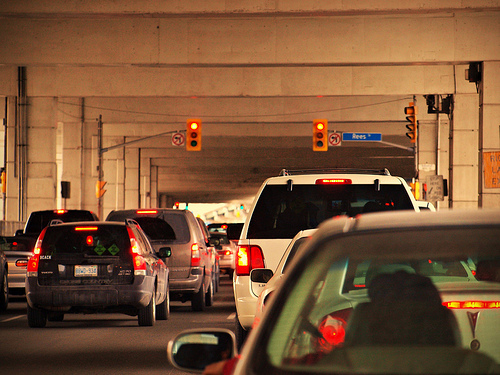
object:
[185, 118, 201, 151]
light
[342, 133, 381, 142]
sign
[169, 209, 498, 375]
car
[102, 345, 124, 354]
street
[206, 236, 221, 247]
hand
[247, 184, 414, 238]
window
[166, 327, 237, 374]
mirror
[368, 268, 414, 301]
driver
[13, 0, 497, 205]
tunnel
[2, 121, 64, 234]
pillar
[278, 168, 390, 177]
van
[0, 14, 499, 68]
bridge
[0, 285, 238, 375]
road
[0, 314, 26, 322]
line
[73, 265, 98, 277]
license plate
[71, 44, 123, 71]
stone